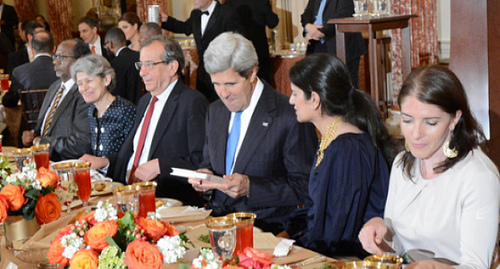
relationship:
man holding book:
[189, 31, 313, 238] [168, 167, 232, 184]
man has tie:
[189, 31, 313, 238] [223, 109, 242, 175]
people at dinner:
[23, 39, 500, 267] [0, 141, 408, 267]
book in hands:
[168, 167, 232, 184] [187, 168, 251, 200]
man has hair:
[189, 31, 313, 238] [204, 31, 261, 79]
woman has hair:
[358, 64, 499, 267] [396, 65, 489, 183]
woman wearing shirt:
[358, 64, 499, 267] [384, 144, 498, 268]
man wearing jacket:
[189, 31, 313, 238] [196, 80, 314, 231]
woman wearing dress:
[289, 53, 391, 259] [295, 129, 389, 260]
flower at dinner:
[44, 200, 186, 267] [0, 141, 408, 267]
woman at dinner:
[358, 64, 499, 267] [0, 141, 408, 267]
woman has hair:
[35, 55, 138, 175] [70, 54, 119, 91]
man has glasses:
[109, 36, 209, 209] [132, 60, 169, 68]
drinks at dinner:
[206, 212, 257, 261] [0, 141, 408, 267]